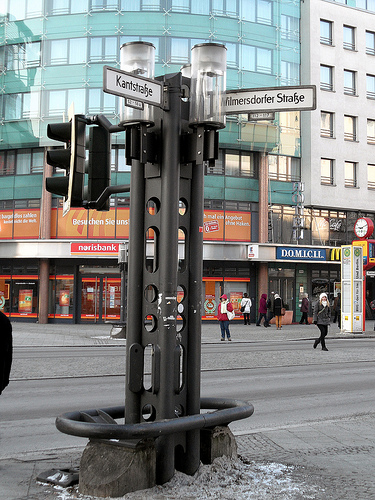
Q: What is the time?
A: 9:10 am.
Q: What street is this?
A: Kanstrafze.